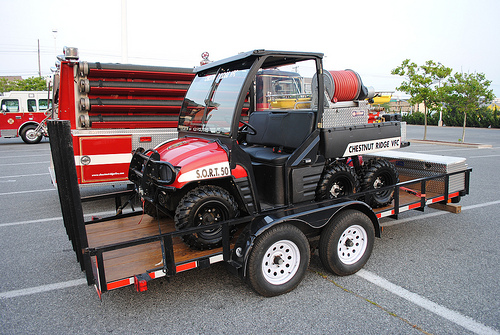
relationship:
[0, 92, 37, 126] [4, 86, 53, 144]
window on bus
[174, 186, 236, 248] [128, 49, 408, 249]
black wheels on atv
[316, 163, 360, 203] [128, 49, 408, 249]
black wheels on atv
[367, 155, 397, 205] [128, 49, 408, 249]
black wheels on atv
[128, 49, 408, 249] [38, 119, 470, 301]
atv on cart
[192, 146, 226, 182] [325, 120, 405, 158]
writing on side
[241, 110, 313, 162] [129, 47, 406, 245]
black seats inside car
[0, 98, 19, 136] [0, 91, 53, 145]
door to bus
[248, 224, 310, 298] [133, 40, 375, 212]
black tire on atv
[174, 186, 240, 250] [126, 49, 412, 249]
black wheels on atv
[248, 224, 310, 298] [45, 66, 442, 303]
black tire on trailer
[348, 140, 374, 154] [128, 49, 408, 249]
word on side of atv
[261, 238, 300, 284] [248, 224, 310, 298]
hubcap on black tire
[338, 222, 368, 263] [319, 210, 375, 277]
hubcap on black tire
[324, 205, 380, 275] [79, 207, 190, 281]
black tire on vehicle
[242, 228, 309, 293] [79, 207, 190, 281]
black tire on vehicle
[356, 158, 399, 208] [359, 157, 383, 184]
black wheels have a lot of tread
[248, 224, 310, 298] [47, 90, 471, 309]
black tire on trailer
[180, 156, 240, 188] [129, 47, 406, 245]
white on side of car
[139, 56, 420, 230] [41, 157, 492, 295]
atv parked on trailer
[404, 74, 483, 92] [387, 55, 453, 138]
leaves on tree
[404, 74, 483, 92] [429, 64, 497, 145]
leaves on tree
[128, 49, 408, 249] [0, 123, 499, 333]
atv on road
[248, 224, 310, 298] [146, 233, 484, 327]
black tire on road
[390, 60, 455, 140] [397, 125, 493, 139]
tree on sidewalk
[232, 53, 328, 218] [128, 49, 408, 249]
door on atv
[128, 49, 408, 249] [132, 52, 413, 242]
atv has wind shield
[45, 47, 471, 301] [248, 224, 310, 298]
cart has black tire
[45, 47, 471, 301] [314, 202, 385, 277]
cart has wheel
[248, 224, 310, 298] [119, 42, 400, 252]
black tire on atv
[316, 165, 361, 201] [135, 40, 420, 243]
black wheels on atv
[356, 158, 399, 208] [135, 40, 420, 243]
black wheels on atv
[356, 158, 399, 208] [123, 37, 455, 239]
black wheels on atv